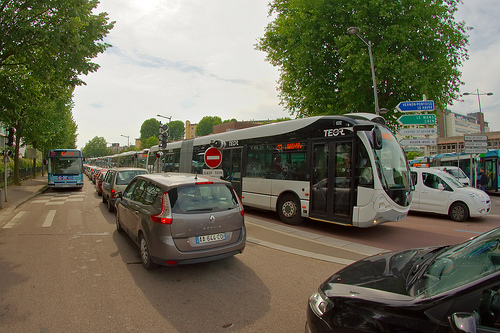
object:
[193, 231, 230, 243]
plate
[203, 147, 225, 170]
sign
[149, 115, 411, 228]
bus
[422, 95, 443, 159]
post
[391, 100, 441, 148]
signs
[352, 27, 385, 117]
pole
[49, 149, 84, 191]
bus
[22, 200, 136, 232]
crossing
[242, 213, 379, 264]
cement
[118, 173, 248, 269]
car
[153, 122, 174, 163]
light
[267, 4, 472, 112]
tree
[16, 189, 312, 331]
road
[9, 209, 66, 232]
lines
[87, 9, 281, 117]
sky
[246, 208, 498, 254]
street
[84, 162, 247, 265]
cars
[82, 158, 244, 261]
line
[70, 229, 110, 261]
stains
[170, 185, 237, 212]
window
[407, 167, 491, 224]
car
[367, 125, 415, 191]
windshield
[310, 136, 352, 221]
door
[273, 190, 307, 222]
wheel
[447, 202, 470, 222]
wheel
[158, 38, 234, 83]
clouds